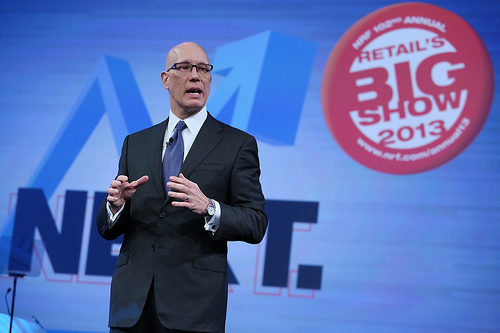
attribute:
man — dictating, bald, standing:
[95, 41, 270, 333]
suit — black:
[95, 105, 272, 333]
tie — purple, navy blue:
[160, 120, 188, 198]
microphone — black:
[166, 136, 176, 147]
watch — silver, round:
[204, 197, 217, 227]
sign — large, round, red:
[320, 2, 497, 177]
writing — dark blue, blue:
[8, 187, 324, 293]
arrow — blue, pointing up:
[0, 27, 318, 274]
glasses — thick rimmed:
[165, 61, 213, 75]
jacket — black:
[95, 109, 268, 332]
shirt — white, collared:
[104, 106, 221, 238]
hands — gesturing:
[106, 171, 207, 219]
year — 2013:
[378, 119, 447, 147]